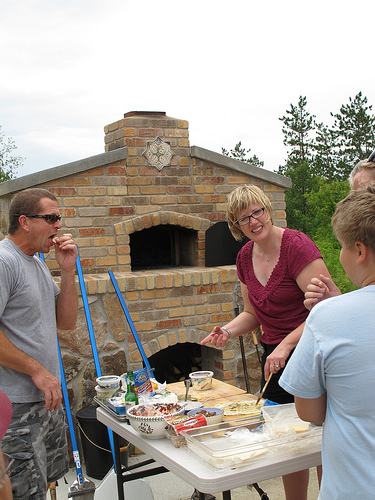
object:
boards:
[159, 373, 247, 405]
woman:
[199, 182, 334, 499]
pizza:
[215, 399, 268, 417]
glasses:
[234, 206, 265, 227]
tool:
[74, 251, 154, 500]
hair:
[224, 185, 274, 240]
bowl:
[127, 400, 183, 440]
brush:
[254, 370, 273, 404]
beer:
[125, 369, 140, 424]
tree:
[273, 95, 324, 233]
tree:
[318, 91, 374, 181]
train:
[115, 212, 246, 270]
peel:
[77, 259, 101, 372]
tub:
[73, 402, 130, 483]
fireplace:
[128, 327, 241, 458]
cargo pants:
[3, 395, 72, 498]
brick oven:
[1, 107, 298, 394]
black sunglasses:
[19, 212, 60, 223]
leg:
[112, 436, 127, 500]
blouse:
[235, 225, 324, 346]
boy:
[276, 184, 375, 462]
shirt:
[1, 232, 65, 406]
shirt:
[279, 280, 373, 498]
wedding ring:
[275, 364, 279, 367]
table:
[99, 362, 324, 500]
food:
[95, 362, 315, 468]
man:
[0, 182, 80, 500]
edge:
[183, 474, 219, 494]